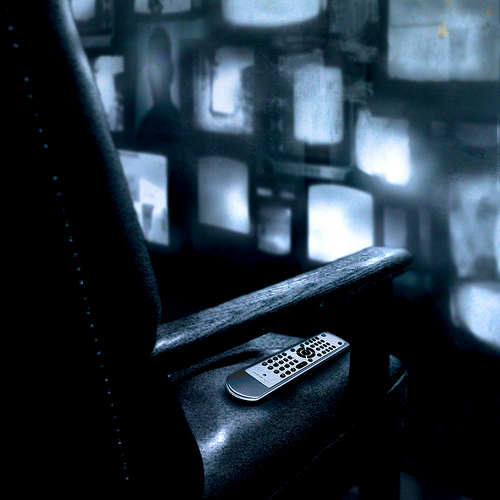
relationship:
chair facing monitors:
[1, 2, 416, 499] [70, 5, 498, 352]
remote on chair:
[223, 329, 352, 406] [6, 7, 456, 499]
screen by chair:
[348, 110, 415, 185] [6, 7, 456, 499]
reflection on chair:
[198, 420, 245, 462] [6, 7, 456, 499]